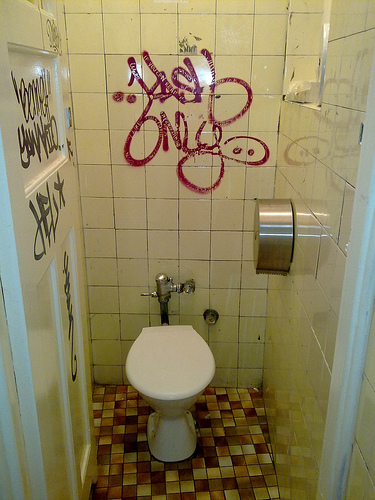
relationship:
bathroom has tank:
[35, 2, 372, 499] [117, 405, 223, 424]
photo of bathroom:
[2, 1, 372, 496] [35, 2, 372, 499]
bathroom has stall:
[35, 2, 372, 499] [54, 1, 371, 498]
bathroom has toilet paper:
[35, 2, 372, 499] [245, 194, 303, 282]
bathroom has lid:
[0, 0, 374, 498] [123, 322, 219, 405]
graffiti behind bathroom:
[101, 32, 277, 197] [0, 0, 374, 498]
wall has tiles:
[35, 2, 372, 499] [45, 1, 371, 499]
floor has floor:
[90, 382, 284, 499] [90, 382, 284, 499]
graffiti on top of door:
[7, 4, 91, 388] [2, 2, 104, 499]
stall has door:
[54, 1, 371, 498] [2, 2, 104, 499]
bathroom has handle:
[0, 0, 374, 498] [140, 289, 160, 301]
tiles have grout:
[45, 1, 371, 499] [269, 0, 300, 203]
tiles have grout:
[45, 1, 371, 499] [97, 3, 131, 265]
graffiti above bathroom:
[101, 32, 277, 197] [0, 0, 374, 498]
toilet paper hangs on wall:
[252, 200, 293, 275] [35, 2, 372, 499]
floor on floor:
[90, 382, 284, 499] [90, 382, 284, 499]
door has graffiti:
[2, 2, 104, 499] [7, 4, 91, 388]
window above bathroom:
[278, 1, 338, 120] [0, 0, 374, 498]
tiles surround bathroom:
[45, 1, 371, 499] [0, 0, 374, 498]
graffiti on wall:
[101, 32, 277, 197] [35, 2, 372, 499]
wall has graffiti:
[35, 2, 372, 499] [101, 32, 277, 197]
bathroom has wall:
[35, 2, 372, 499] [35, 2, 372, 499]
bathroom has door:
[35, 2, 372, 499] [2, 2, 104, 499]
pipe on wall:
[155, 304, 175, 325] [35, 2, 372, 499]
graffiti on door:
[7, 4, 91, 388] [2, 2, 104, 499]